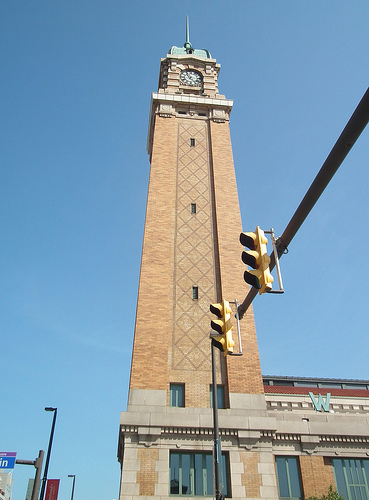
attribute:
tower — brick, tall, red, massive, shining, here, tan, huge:
[133, 33, 264, 385]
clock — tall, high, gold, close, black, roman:
[170, 62, 217, 100]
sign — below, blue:
[5, 446, 24, 480]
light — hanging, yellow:
[230, 219, 293, 312]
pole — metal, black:
[302, 127, 353, 193]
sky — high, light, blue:
[14, 60, 137, 256]